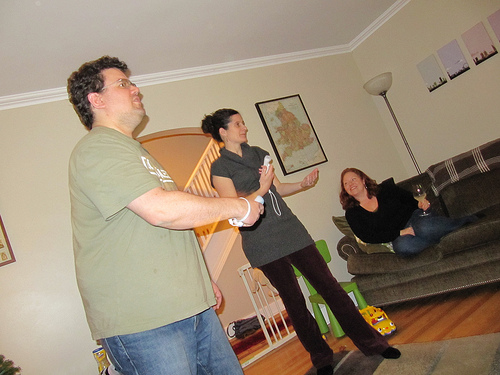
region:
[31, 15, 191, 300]
A person standing in the floor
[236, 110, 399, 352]
A woman standing in the floor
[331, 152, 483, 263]
A woman sitting in the couch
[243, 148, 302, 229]
Peoples playing with electronic devices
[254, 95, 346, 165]
Photo frame hanging on the wall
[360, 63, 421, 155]
Metal pole with night lamp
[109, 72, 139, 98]
A person wearing specs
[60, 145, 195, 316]
A person wearing green color round neck t-shirt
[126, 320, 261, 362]
A person wearing blue color jean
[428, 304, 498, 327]
Wooden type floor tiles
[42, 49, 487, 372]
Two people in the image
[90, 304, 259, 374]
Man is wearing blue jeans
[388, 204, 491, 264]
Woman is wearing blue jeans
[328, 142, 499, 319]
Woman is laying on a couch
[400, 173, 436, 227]
Woman is holding a wine glass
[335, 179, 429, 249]
Woman is wearing a black shirt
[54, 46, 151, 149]
A side view of a man's head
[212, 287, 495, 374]
The floor is made of hardwood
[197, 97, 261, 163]
A side view of a woman's head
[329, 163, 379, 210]
Woman in the background is smiling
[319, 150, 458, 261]
the woman on the couch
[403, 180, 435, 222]
the woman holding the glass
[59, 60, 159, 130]
the man wearing glasses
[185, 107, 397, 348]
the woman playing video games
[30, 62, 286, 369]
the man playing video games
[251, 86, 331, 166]
the picture on the wall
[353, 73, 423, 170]
the lamp behind the couch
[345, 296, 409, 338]
toy behind the woman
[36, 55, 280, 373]
the man playing wii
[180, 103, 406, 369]
the woman playing wii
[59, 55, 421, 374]
Two people playing the wii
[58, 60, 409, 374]
A man and a woman standing up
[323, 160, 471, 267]
A woman curled up on the couch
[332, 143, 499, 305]
A dark colored sofa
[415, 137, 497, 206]
A blanket on the back of a sofa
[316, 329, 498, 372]
An area rug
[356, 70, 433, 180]
A floor lamp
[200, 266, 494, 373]
Hardwood floors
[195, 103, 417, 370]
A woman holding a wii controller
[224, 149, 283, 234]
White wii controllers